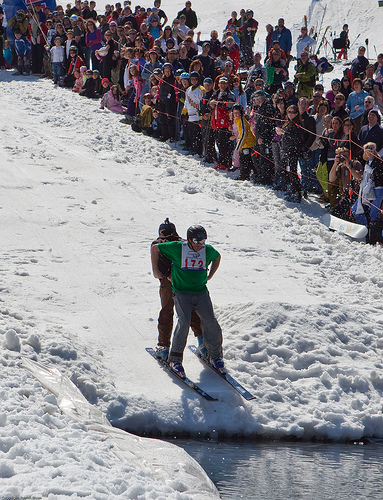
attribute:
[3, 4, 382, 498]
snow — white 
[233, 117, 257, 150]
jacket — yellow 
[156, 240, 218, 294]
shirt — green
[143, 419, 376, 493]
water — small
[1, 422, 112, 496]
snow — white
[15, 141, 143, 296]
snow — white 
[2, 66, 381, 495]
snow — white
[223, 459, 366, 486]
ripples — big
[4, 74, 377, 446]
snow — white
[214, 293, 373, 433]
snow pile — white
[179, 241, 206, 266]
bib — man's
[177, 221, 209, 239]
helmet — black